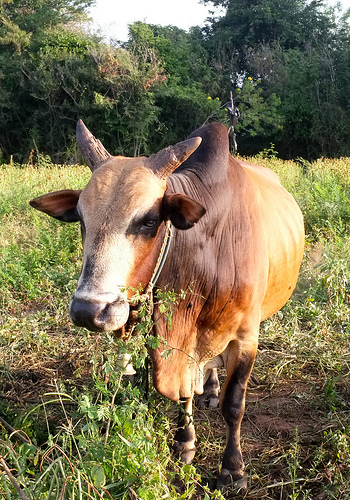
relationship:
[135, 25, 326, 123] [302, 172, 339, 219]
trees behind grass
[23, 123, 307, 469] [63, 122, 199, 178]
cow has horns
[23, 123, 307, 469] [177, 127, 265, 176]
cow has hump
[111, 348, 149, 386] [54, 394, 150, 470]
bell behind bushes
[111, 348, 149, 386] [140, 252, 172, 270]
bell on rope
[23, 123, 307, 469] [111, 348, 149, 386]
cow has bell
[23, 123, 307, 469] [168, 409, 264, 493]
cow has feet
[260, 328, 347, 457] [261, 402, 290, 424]
ground has dirt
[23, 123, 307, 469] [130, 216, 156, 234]
cow has left eye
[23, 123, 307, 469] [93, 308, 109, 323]
cow has nostril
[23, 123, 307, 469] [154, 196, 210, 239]
cow has ear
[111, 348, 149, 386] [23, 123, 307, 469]
bell on cow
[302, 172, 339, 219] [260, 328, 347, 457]
grass on ground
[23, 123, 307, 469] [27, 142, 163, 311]
cow has head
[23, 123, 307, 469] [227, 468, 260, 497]
cow has hoof